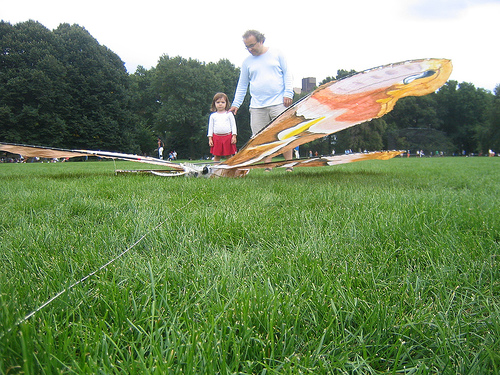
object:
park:
[16, 14, 491, 369]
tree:
[2, 16, 71, 156]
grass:
[9, 162, 496, 369]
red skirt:
[209, 133, 238, 156]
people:
[407, 150, 411, 158]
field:
[2, 159, 498, 371]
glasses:
[244, 42, 258, 49]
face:
[243, 35, 264, 55]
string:
[7, 184, 209, 374]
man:
[226, 27, 298, 177]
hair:
[211, 94, 229, 111]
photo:
[4, 3, 499, 374]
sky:
[319, 14, 494, 49]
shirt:
[205, 111, 239, 138]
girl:
[207, 90, 234, 178]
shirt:
[231, 54, 288, 108]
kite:
[9, 49, 455, 177]